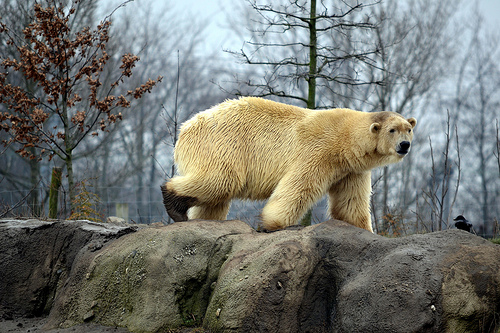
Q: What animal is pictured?
A: A bear.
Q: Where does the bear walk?
A: On a large rock.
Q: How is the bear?
A: Massive with cream colored fur.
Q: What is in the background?
A: Tall trees.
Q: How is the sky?
A: Gray and gloomy.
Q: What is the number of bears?
A: One.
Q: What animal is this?
A: Bear.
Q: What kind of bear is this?
A: Polar.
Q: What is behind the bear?
A: Trees.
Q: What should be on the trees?
A: Leaves.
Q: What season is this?
A: Winter.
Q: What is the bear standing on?
A: Rocky ledge.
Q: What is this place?
A: Zoo.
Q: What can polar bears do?
A: Swim.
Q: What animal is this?
A: Bear.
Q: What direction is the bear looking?
A: Right.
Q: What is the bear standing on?
A: Rock.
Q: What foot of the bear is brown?
A: Back right.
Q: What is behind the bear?
A: Trees.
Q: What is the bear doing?
A: Walking.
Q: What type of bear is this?
A: Polar bear.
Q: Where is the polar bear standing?
A: On the rocks.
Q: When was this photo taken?
A: During the day.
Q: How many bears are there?
A: One.